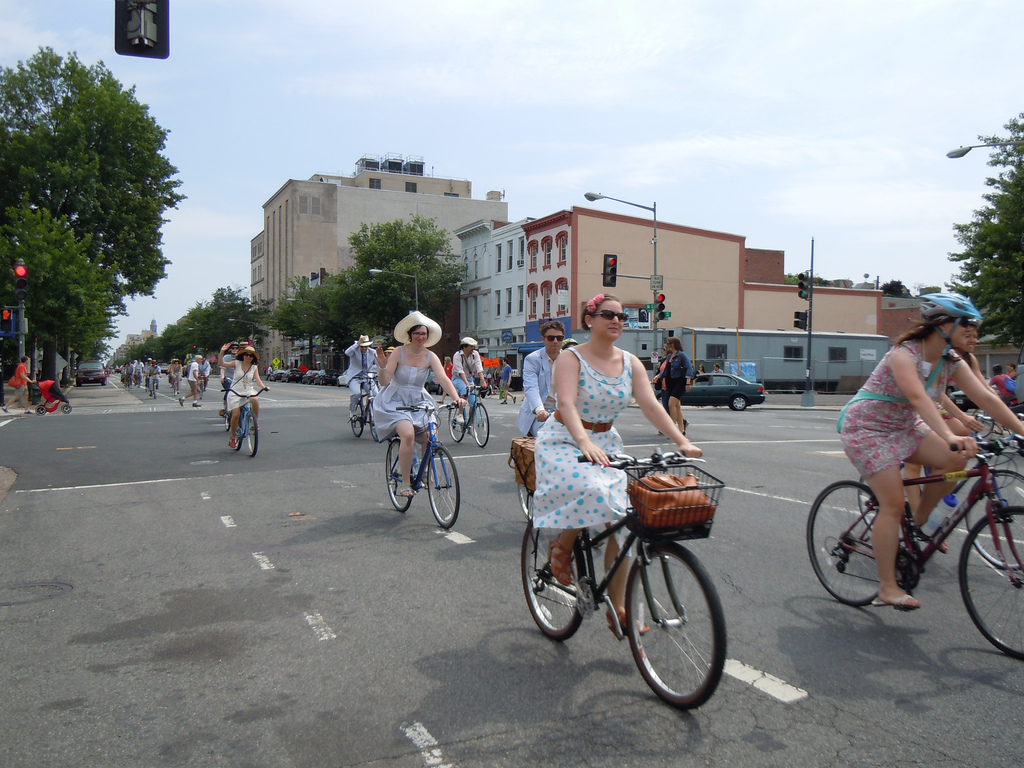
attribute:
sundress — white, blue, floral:
[494, 348, 687, 537]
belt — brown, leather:
[533, 402, 676, 457]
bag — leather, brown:
[615, 469, 773, 549]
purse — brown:
[606, 441, 751, 580]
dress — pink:
[823, 351, 990, 546]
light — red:
[71, 7, 182, 49]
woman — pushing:
[10, 353, 43, 403]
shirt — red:
[2, 357, 29, 381]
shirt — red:
[7, 365, 34, 381]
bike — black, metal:
[501, 433, 770, 758]